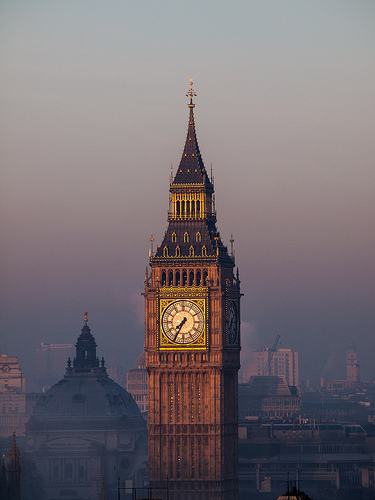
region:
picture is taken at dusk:
[0, 160, 360, 474]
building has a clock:
[150, 296, 218, 356]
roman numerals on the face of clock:
[165, 304, 201, 343]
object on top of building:
[187, 82, 203, 106]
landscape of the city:
[238, 339, 360, 455]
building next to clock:
[43, 310, 148, 499]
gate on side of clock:
[119, 481, 167, 499]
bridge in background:
[264, 421, 371, 440]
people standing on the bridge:
[274, 418, 301, 427]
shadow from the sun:
[245, 359, 278, 406]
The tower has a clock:
[109, 151, 304, 409]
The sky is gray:
[36, 195, 372, 429]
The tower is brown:
[146, 280, 254, 480]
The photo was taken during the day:
[26, 256, 371, 448]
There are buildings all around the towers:
[18, 275, 373, 480]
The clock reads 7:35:
[136, 243, 284, 400]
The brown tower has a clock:
[136, 264, 270, 391]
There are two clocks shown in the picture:
[141, 266, 282, 375]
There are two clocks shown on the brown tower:
[131, 250, 314, 405]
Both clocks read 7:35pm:
[143, 283, 273, 374]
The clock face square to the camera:
[160, 298, 206, 347]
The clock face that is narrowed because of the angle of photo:
[226, 296, 241, 346]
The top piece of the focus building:
[186, 74, 196, 107]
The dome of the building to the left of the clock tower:
[22, 301, 146, 427]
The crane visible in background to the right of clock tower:
[255, 328, 283, 376]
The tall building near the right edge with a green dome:
[340, 335, 360, 383]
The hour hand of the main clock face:
[174, 316, 187, 330]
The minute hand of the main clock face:
[172, 316, 188, 343]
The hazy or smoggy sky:
[0, 0, 373, 356]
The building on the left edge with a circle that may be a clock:
[1, 354, 29, 438]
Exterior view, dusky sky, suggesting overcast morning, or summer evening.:
[4, 5, 368, 495]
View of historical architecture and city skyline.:
[1, 7, 374, 492]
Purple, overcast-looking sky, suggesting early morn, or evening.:
[30, 133, 111, 282]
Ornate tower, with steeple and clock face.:
[145, 97, 244, 490]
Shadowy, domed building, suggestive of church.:
[24, 316, 135, 489]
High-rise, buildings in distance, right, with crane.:
[262, 323, 313, 377]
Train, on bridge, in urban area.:
[242, 405, 358, 482]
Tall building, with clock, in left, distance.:
[0, 353, 18, 420]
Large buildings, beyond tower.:
[128, 380, 333, 427]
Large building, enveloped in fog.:
[336, 334, 366, 387]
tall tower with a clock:
[141, 57, 253, 497]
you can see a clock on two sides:
[150, 291, 245, 354]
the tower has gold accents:
[163, 192, 209, 260]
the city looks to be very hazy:
[2, 128, 372, 358]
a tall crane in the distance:
[254, 326, 288, 381]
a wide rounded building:
[11, 314, 142, 499]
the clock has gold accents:
[155, 290, 211, 352]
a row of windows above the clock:
[146, 266, 214, 285]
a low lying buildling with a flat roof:
[258, 419, 366, 439]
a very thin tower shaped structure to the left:
[0, 428, 28, 499]